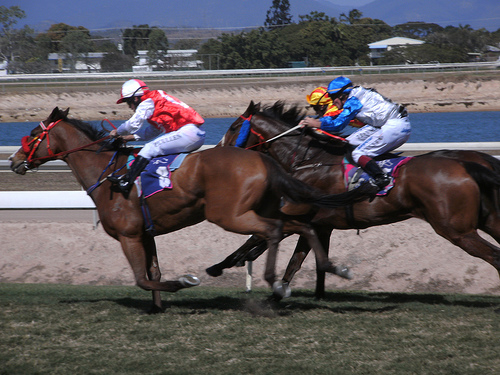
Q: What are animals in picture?
A: Horses.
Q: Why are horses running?
A: In a race.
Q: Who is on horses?
A: Jockeys.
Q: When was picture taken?
A: Daytime.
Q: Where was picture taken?
A: Race track.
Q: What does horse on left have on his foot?
A: Horseshoe.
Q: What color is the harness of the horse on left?
A: Red.